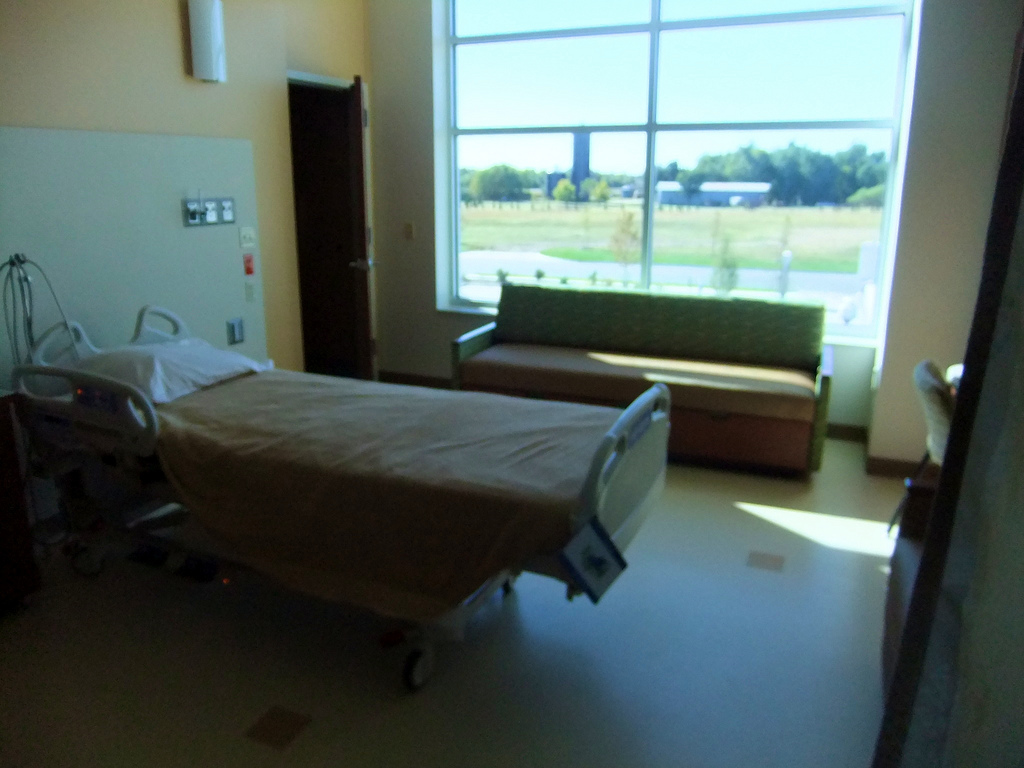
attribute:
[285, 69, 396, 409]
door — half open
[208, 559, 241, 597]
dot — red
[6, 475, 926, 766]
floor — brown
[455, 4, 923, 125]
sky — clear, blue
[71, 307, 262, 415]
pillow — white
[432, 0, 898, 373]
panel — clean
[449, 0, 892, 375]
window — large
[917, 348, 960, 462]
desk chair — back